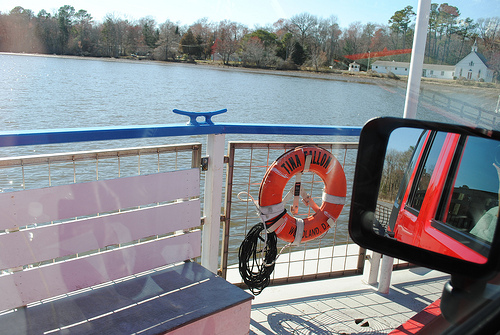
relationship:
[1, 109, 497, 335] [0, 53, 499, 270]
ferry on water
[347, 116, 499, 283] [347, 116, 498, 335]
mirror on car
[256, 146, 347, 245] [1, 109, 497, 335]
lifesaver on ferry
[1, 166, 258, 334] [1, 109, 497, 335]
fence on ferry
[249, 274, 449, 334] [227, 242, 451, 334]
shadow on floor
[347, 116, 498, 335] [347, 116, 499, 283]
car in mirror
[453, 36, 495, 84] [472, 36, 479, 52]
church has steeple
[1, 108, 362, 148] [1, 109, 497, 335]
rail on ferry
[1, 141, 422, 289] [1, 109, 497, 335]
fence on ferry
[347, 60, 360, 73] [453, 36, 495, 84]
gazebo by church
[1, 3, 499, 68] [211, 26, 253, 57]
trees has leaves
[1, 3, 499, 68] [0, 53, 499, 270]
trees along water